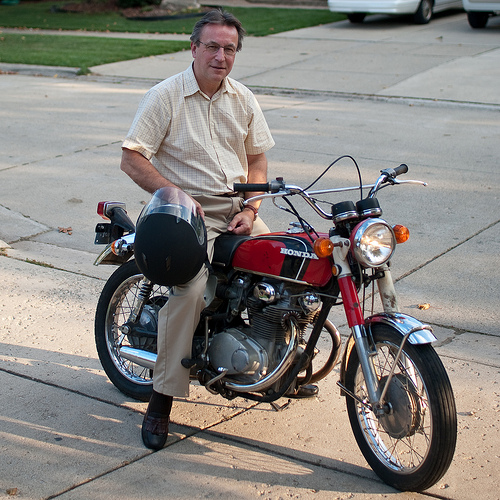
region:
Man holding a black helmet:
[131, 211, 210, 278]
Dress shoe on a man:
[146, 399, 168, 451]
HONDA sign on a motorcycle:
[277, 245, 327, 260]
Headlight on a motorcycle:
[344, 217, 396, 263]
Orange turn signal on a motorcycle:
[393, 222, 413, 242]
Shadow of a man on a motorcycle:
[3, 346, 114, 490]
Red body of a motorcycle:
[242, 225, 332, 280]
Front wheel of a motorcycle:
[338, 312, 453, 489]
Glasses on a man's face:
[196, 40, 241, 55]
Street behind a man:
[22, 77, 492, 227]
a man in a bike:
[112, 117, 370, 487]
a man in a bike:
[160, 165, 324, 437]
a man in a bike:
[80, 65, 324, 382]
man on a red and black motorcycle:
[91, 6, 487, 494]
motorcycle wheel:
[336, 310, 458, 491]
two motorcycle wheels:
[92, 263, 464, 490]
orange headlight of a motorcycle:
[313, 238, 333, 255]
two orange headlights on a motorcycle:
[312, 223, 413, 261]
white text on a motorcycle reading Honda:
[279, 242, 320, 262]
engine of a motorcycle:
[198, 278, 332, 404]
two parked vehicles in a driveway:
[325, 0, 499, 38]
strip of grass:
[3, 27, 190, 78]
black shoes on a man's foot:
[138, 393, 173, 452]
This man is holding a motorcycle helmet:
[133, 190, 195, 301]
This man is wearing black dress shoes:
[146, 390, 177, 460]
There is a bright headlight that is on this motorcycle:
[341, 212, 403, 301]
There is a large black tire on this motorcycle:
[354, 314, 467, 489]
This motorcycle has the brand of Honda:
[276, 234, 328, 280]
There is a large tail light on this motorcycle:
[89, 195, 130, 226]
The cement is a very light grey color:
[433, 206, 458, 256]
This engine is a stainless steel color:
[234, 294, 297, 402]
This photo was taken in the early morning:
[123, 95, 397, 469]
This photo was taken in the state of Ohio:
[117, 43, 427, 435]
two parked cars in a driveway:
[317, 1, 498, 70]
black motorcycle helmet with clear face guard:
[135, 184, 207, 286]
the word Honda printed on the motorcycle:
[272, 243, 320, 265]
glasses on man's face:
[197, 39, 245, 56]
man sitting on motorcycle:
[87, 8, 462, 498]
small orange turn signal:
[314, 234, 337, 260]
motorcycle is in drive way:
[84, 162, 464, 491]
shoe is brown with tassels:
[137, 389, 175, 457]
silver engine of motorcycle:
[215, 292, 285, 400]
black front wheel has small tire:
[345, 329, 464, 496]